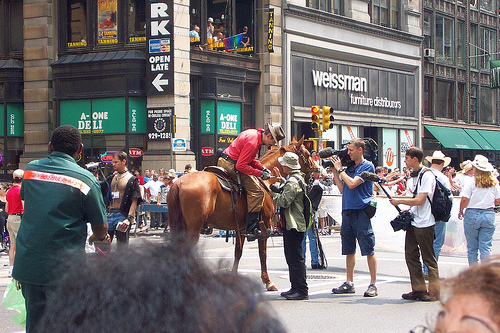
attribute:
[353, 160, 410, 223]
mic — large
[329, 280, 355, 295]
shoe — grey, tennis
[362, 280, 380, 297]
shoe — grey, tennis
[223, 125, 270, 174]
shirt — red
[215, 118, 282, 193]
man shirt — red, collard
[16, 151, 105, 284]
shirt — green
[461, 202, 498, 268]
jeans — blue, denim